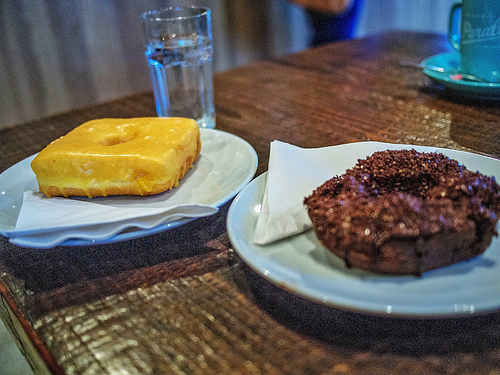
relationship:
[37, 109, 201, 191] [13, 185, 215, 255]
doughnut next to napkin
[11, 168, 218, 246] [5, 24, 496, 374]
napkin on table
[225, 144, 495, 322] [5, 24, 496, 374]
plate on table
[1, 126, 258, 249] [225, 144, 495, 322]
plate next to plate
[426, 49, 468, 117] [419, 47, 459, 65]
utensil on plate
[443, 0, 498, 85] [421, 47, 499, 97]
mug on plate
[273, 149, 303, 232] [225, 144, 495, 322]
napkin on plate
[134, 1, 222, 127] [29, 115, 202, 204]
glass next to doughnut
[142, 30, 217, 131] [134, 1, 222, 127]
water in glass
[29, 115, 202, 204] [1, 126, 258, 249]
doughnut on top of plate